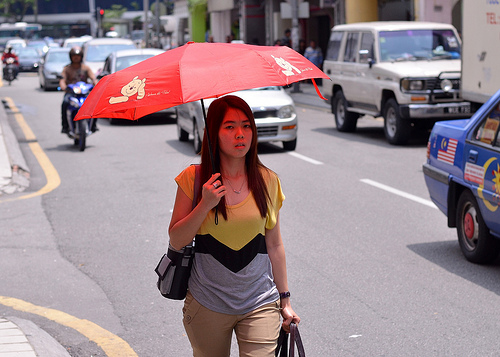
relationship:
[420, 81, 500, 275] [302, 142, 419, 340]
cab driving on road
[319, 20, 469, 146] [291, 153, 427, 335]
truck driving on road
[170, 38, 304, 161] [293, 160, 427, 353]
vehicle driving on road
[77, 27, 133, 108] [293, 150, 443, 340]
vehicle driving on road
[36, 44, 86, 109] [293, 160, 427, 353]
vehicle driving on road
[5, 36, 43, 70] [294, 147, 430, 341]
vehicle driving on road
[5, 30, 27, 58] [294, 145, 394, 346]
vehicle driving on road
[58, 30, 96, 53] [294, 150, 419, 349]
vehicle driving on road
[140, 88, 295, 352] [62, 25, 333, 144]
woman holding an umbrella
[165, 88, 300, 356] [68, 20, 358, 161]
woman holding an umbrella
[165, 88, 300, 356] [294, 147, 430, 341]
woman walking on road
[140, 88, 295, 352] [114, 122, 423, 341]
woman walking on road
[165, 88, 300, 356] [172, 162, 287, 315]
woman wearing blouse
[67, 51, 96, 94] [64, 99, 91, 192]
person on motorized bike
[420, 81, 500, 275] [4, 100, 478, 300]
cab on street